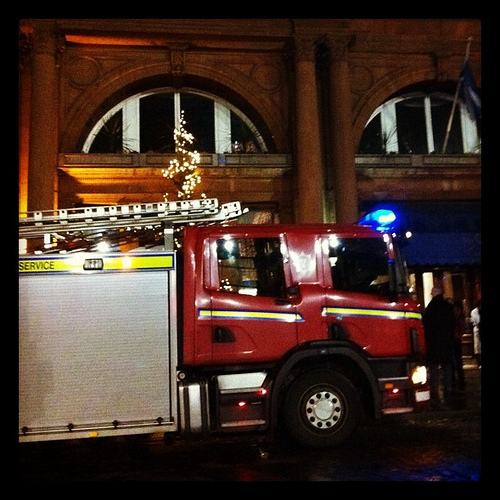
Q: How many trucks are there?
A: One.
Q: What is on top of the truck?
A: Ladder.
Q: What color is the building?
A: Brown.